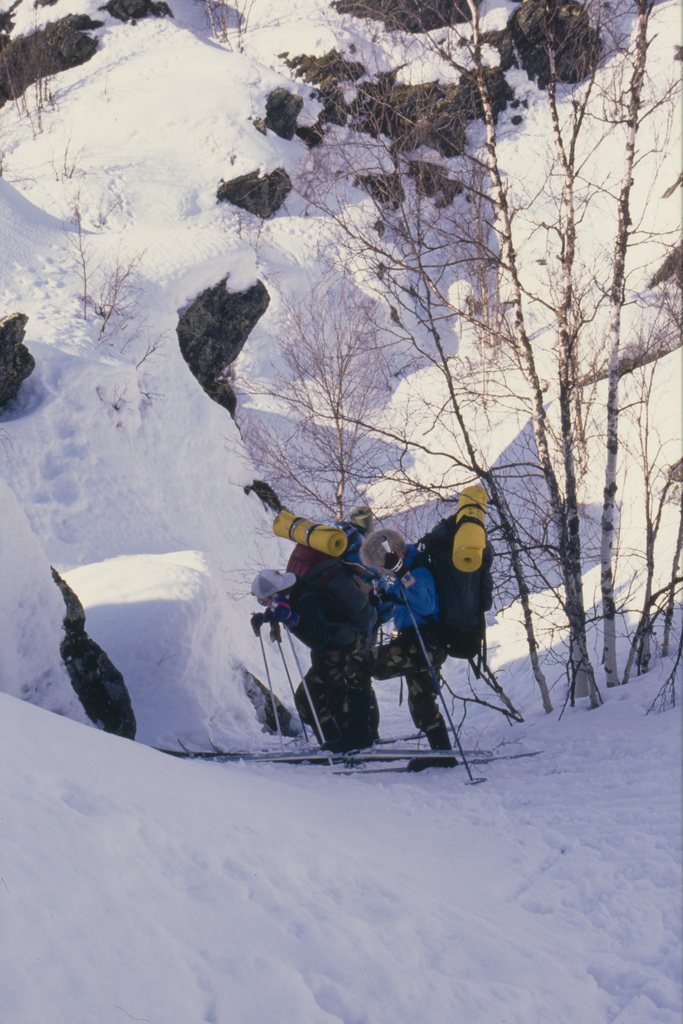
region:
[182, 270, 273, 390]
rock is covered in snow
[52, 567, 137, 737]
rock is covered in snow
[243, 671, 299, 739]
rock is covered in snow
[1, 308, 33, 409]
rock is covered in snow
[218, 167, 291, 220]
rock is covered in snow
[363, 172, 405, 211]
rock is covered in snow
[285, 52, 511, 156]
rock is covered in snow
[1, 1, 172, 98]
rock is covered in snow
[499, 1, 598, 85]
rock is covered in snow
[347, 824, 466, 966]
white snow on the ground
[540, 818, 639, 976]
white snow on the ground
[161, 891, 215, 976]
white snow on the ground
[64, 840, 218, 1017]
white snow on the ground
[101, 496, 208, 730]
white snow on the ground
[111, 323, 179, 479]
white snow on the ground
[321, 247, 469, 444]
white snow on the ground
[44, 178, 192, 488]
white snow on the ground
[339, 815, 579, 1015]
white snow on the ground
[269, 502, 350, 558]
one of two yellow mats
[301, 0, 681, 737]
the trees are aspens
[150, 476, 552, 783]
two cross country skiers packing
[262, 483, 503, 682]
the skiers are carrying large packs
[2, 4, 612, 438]
large rocks stick out of the snow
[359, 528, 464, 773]
this skier is wearing a blue parka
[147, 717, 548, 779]
the skies are being used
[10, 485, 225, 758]
the skiers are about enter this passage way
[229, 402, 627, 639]
rocks are casting these shadows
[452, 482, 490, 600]
yellow rolled yoga mat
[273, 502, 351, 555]
yellow rolled yoga mat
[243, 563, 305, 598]
white baseball hat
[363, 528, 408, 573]
brown fur hat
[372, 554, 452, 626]
teal blue jacket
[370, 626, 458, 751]
camo snow pants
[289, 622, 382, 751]
camo snow pants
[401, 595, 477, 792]
metal ski pole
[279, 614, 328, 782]
metal ski pole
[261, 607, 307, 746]
metal ski pole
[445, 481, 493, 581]
Yellow object on backpack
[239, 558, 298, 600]
White hat on man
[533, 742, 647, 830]
Tracks in the snow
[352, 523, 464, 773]
Person in a blue jacket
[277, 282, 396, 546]
Trees with no leaves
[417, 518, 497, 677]
Green backpack on a person